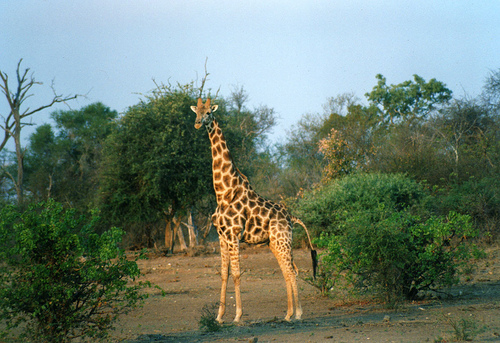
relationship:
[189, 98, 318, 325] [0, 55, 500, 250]
giraffe in bushes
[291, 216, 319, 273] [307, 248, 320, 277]
tail with hair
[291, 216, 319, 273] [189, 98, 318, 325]
tail of giraffe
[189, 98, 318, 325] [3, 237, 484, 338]
giraffe in dirt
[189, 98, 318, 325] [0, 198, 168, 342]
giraffe between bush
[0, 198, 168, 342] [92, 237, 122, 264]
bush with leaves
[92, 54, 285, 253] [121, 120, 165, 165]
tree with leaves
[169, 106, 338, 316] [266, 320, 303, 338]
giraffe standing in dirt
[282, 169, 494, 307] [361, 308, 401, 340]
bush in dirt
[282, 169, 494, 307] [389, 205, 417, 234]
bush with leafs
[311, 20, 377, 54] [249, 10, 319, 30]
sky with clouds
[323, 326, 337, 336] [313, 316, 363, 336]
rocks in dirt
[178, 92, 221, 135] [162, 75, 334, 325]
head of giraffe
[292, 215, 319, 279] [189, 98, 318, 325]
tail of giraffe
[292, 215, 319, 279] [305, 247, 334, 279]
tail with hair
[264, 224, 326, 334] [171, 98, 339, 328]
legs of giraffe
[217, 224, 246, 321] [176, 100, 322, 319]
legs of giraffe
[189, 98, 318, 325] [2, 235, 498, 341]
giraffe on field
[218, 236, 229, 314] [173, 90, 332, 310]
legs of giraffe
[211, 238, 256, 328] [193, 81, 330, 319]
legs of giraffe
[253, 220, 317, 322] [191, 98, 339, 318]
legs of giraffe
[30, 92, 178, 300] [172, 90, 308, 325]
trees around giraffe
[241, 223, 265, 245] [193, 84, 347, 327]
belly of giraffe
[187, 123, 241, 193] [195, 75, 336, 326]
neck of giraffe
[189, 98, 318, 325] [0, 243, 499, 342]
giraffe standing on dirt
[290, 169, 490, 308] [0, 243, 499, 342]
bush in dirt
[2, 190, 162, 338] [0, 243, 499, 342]
bush in dirt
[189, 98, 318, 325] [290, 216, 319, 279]
giraffe has tail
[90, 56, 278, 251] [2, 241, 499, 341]
tree in field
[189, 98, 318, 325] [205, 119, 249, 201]
giraffe has neck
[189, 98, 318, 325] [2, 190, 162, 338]
giraffe standing next to bush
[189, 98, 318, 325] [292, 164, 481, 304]
giraffe standing next to bush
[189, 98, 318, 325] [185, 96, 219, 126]
giraffe has head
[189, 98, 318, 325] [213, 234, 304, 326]
giraffe has legs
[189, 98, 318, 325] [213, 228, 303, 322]
giraffe has legs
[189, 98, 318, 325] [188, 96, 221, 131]
giraffe has face